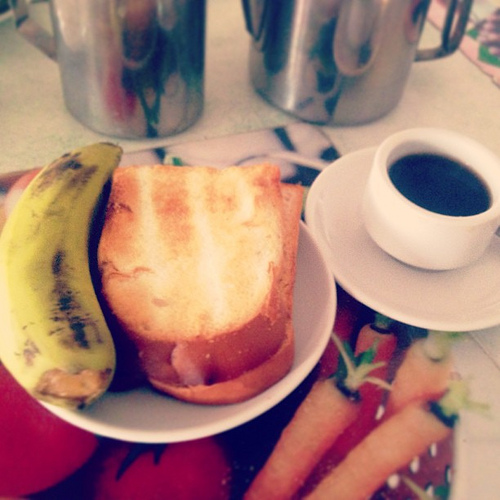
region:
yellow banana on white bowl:
[2, 142, 135, 406]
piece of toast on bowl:
[127, 155, 276, 365]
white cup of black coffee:
[355, 149, 477, 256]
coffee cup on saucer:
[375, 125, 498, 274]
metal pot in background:
[50, 9, 205, 140]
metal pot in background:
[250, 3, 411, 123]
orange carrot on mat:
[284, 380, 344, 485]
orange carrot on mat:
[348, 423, 419, 486]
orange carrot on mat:
[358, 329, 390, 379]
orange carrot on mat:
[399, 345, 464, 405]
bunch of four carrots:
[295, 323, 465, 497]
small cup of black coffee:
[367, 133, 498, 268]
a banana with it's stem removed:
[0, 137, 119, 408]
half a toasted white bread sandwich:
[98, 161, 295, 397]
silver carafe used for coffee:
[245, 9, 461, 128]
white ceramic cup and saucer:
[315, 137, 499, 321]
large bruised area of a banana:
[39, 242, 96, 368]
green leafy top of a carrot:
[334, 346, 384, 397]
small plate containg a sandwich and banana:
[15, 143, 320, 442]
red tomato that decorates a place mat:
[99, 445, 244, 499]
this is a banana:
[6, 169, 156, 321]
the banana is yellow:
[4, 218, 70, 325]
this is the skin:
[20, 306, 75, 381]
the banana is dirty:
[37, 243, 154, 418]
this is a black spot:
[34, 249, 126, 394]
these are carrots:
[337, 384, 428, 498]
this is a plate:
[153, 365, 271, 490]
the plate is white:
[107, 344, 182, 481]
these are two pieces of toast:
[222, 276, 264, 439]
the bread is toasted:
[148, 241, 203, 394]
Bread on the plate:
[131, 172, 298, 394]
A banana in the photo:
[17, 227, 115, 382]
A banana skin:
[12, 147, 119, 374]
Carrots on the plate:
[290, 346, 461, 489]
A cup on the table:
[360, 158, 476, 255]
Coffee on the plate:
[405, 159, 467, 213]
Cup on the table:
[279, 52, 405, 95]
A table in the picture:
[210, 134, 331, 169]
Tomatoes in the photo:
[2, 452, 159, 492]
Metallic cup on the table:
[305, 14, 396, 101]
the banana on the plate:
[27, 120, 145, 412]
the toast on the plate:
[105, 152, 300, 351]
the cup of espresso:
[357, 113, 498, 277]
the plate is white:
[46, 156, 333, 432]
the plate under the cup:
[315, 130, 498, 338]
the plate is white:
[309, 110, 499, 347]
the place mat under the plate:
[16, 156, 443, 486]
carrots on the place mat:
[258, 343, 450, 497]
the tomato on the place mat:
[102, 447, 236, 499]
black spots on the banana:
[42, 245, 89, 350]